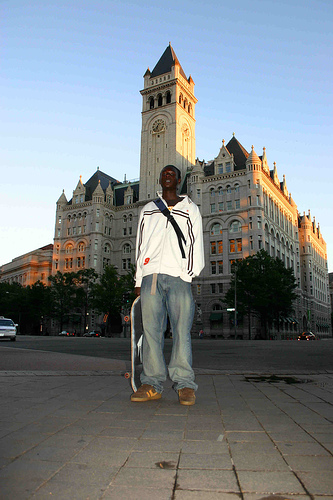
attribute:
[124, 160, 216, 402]
man — standing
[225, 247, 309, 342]
tree — green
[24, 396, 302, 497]
sidewalk — paved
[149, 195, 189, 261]
strap — black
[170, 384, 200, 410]
shoe — brown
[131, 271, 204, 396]
jeans — blue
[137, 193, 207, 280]
white jacket — black